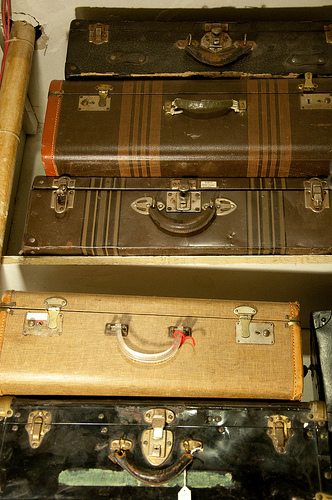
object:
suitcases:
[64, 3, 330, 77]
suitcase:
[1, 393, 331, 500]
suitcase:
[0, 288, 306, 403]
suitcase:
[40, 76, 331, 174]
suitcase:
[20, 173, 331, 260]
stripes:
[112, 189, 122, 255]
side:
[41, 74, 68, 174]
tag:
[173, 466, 194, 500]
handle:
[114, 320, 186, 367]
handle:
[143, 197, 214, 237]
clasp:
[24, 408, 51, 450]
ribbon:
[173, 329, 196, 349]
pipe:
[0, 22, 34, 252]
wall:
[35, 0, 65, 82]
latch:
[139, 411, 173, 469]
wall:
[1, 250, 329, 288]